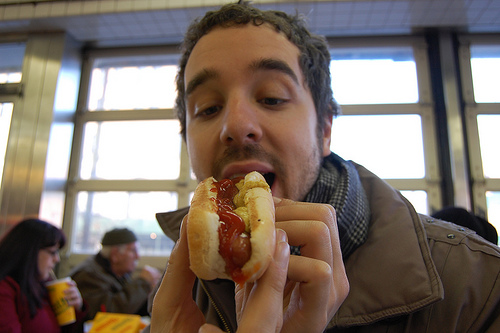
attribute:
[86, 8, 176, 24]
roof — white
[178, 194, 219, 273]
bun — tan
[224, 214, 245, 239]
ketchup — red, dripping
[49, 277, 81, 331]
cup — yellow, disposable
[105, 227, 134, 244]
hat — maroon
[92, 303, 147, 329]
box — yellow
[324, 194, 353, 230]
shirt — checkered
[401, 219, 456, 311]
jacket — brown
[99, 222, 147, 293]
man — old, older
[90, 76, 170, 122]
sky — clear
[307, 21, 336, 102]
hair — brown, short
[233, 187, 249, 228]
mustard — yellow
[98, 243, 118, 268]
collar — brown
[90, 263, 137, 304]
coat — brown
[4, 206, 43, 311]
hair — brown, long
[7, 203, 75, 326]
woman — drinking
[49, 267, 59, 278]
straw — white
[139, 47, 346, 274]
guy — eating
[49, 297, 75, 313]
letters — green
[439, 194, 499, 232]
hat — dark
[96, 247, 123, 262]
hair — grey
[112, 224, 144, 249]
cap — brown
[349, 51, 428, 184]
window — big